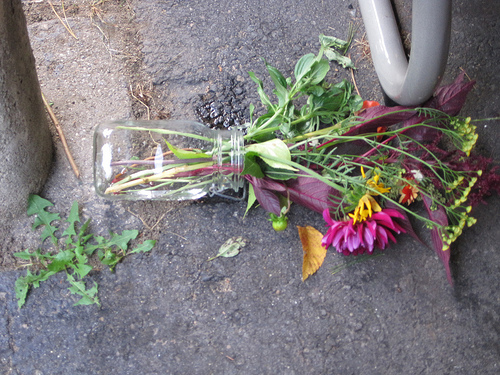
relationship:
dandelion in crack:
[7, 188, 149, 318] [5, 193, 182, 291]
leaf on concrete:
[296, 221, 333, 278] [5, 2, 497, 367]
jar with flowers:
[87, 110, 250, 211] [110, 35, 494, 255]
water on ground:
[189, 74, 260, 133] [4, 8, 498, 365]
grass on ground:
[124, 31, 186, 223] [4, 8, 498, 365]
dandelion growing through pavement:
[7, 188, 149, 318] [5, 2, 497, 367]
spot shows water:
[188, 70, 264, 131] [189, 74, 260, 133]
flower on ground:
[319, 202, 411, 257] [4, 8, 498, 365]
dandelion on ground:
[0, 188, 157, 309] [4, 8, 498, 365]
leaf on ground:
[296, 221, 333, 278] [4, 8, 498, 365]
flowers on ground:
[333, 165, 395, 220] [4, 8, 498, 365]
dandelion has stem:
[0, 188, 157, 309] [52, 250, 83, 273]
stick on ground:
[42, 87, 95, 195] [4, 8, 498, 365]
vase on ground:
[92, 108, 245, 203] [4, 8, 498, 365]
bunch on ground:
[246, 30, 491, 258] [4, 8, 498, 365]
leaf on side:
[296, 221, 333, 278] [7, 197, 499, 361]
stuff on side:
[211, 218, 327, 276] [7, 197, 499, 361]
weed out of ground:
[14, 187, 156, 314] [4, 8, 498, 365]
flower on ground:
[353, 170, 389, 225] [4, 8, 498, 365]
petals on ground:
[312, 202, 410, 253] [4, 8, 498, 365]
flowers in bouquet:
[419, 111, 491, 250] [284, 94, 492, 256]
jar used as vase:
[87, 110, 250, 211] [92, 108, 245, 203]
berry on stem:
[270, 216, 290, 231] [278, 184, 299, 219]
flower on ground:
[391, 173, 423, 204] [4, 8, 498, 365]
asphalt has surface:
[4, 4, 498, 367] [2, 4, 497, 368]